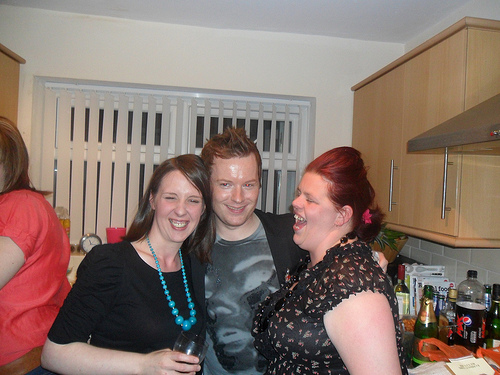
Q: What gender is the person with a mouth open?
A: Female.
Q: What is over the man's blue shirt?
A: A black blazer.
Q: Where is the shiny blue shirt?
A: On the man.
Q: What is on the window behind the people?
A: White blinds.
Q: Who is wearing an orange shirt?
A: A woman.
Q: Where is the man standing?
A: Between two women.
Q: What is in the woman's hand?
A: A clear glass.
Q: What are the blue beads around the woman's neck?
A: A necklace.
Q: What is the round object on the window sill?
A: A small clock.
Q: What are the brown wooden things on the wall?
A: Kitchen cupboards.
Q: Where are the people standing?
A: In a kitchen.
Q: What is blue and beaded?
A: A necklace.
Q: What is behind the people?
A: A window.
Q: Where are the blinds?
A: On the window.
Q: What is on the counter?
A: Drinks.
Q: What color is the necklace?
A: Blue.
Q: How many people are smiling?
A: Three.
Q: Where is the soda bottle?
A: On the right.